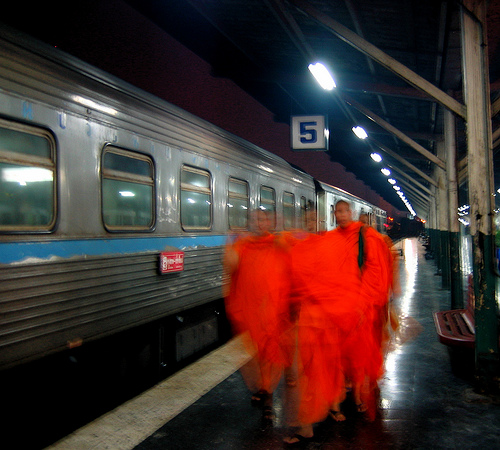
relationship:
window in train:
[93, 139, 165, 231] [21, 69, 155, 334]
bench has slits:
[441, 273, 485, 340] [435, 306, 463, 339]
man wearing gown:
[224, 227, 288, 394] [289, 226, 346, 403]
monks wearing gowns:
[219, 201, 389, 413] [289, 226, 346, 403]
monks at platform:
[219, 201, 389, 413] [189, 401, 240, 432]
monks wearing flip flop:
[219, 201, 389, 413] [276, 427, 316, 445]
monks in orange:
[219, 201, 389, 413] [289, 226, 346, 403]